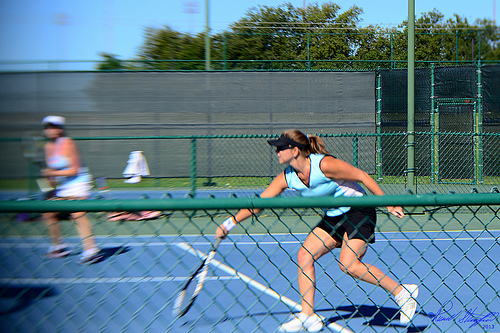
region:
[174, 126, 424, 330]
woman swinging tennis racket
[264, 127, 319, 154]
black sun visor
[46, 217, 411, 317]
green chain link fence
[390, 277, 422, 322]
white tennis shoe on foot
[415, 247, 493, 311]
blue tennis court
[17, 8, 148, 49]
clear cloudless blue sky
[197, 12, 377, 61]
tall trees with green leaves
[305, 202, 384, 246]
short black tennis skirt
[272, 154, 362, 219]
light blue and white top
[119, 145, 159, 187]
towel hanging on fence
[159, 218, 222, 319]
Tennis racket.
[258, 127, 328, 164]
Visor worn by a woman.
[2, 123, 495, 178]
Green metal fence in the background.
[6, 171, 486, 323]
Green metal fence in the foreground.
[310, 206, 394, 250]
Black skort worn by the woman in front.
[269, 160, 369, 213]
Light blue vneck tank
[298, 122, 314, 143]
Blue band for pony tail.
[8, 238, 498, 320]
Blue tennis court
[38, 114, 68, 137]
White cap worn by woman in background.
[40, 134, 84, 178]
Tank top worn by woman in background.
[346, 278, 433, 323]
part of a meshed fence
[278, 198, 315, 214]
part of a post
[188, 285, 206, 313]
edge of a racket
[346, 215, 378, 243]
part of a skirt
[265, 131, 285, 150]
part of a cap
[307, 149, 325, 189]
part of a vest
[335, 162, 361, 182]
part of a bicep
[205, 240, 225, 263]
handle of a racket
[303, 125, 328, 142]
hair of the lady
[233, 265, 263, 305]
part of a white line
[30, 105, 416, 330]
Doubles tennis partners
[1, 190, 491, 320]
Low green chainlink fence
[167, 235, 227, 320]
Black and white tennis raquet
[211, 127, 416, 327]
Female tennis player in black visor and black shorts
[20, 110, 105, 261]
Female tennis player in white skirt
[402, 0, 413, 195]
Green lighting pole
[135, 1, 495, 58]
Trees outside the courts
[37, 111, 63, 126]
White hat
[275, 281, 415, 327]
White tennis shoes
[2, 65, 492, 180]
Tall fence with covering surrounding courts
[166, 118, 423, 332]
person in blue tank top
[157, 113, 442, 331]
person wearing black visor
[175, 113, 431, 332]
person holding tennis racket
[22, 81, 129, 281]
person in blue tank top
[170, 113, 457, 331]
person wearing white shoes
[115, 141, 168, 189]
white towel hanging on fence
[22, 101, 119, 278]
person wearing white hat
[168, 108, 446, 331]
person wearing black shorts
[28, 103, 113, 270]
person wearing white shorts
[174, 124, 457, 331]
person about to hit a tennis ball